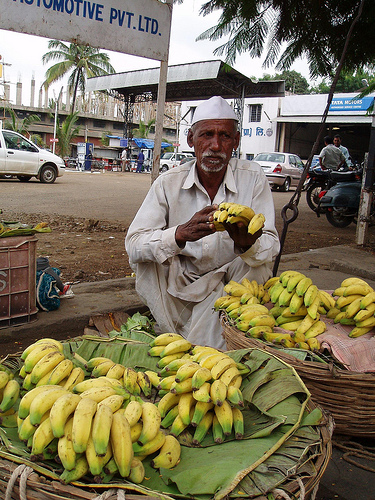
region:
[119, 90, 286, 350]
The man is dressed in white.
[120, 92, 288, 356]
The man is holding a bunch of bananas.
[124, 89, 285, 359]
The man is wearing a hat.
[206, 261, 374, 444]
The large basket has bananas on top.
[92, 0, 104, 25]
The letter is blue.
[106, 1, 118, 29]
The letter is blue.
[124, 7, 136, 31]
The letter is blue.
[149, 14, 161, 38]
The letter is blue.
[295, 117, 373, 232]
The men are standing by the motorcycle.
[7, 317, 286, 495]
bunches of bananas for sale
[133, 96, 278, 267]
man holding bananas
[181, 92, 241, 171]
man wearing a white hat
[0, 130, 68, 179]
white vehicle on the road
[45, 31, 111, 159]
tall palm tree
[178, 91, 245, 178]
man with a white beard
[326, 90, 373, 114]
blue sign on the building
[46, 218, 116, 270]
rocky dirt ground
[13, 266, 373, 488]
bananas sitting on stands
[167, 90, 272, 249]
Man wearing white cap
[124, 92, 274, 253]
Man in white cap holding bananas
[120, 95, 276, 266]
Man wearing white shirt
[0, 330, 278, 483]
yellow bananas sitting on banana leaves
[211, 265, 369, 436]
wicker basket full of yellow bananas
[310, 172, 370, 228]
rear tire of blue motor scooter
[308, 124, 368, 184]
man in white shirt next to man in blue shirt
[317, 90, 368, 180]
blue sign on front of building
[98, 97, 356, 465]
man in white selling bananas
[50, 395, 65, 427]
yellow banana in banana bunch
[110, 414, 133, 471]
yellow banana in banana bunch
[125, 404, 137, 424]
yellow banana in banana bunch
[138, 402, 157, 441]
yellow banana in banana bunch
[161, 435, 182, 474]
yellow banana in banana bunch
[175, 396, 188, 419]
yellow banana in banana bunch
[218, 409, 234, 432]
yellow banana in banana bunch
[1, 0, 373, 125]
bright lights over trees and buildings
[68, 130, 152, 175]
people standing in front on an outdoor cafe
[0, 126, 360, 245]
vehicles parked on flat paved road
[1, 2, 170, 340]
sign above dirt patch with litter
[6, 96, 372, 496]
man with display of bunches of bananas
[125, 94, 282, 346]
man holding bananas with both hands in front of body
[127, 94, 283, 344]
man in loose clothing by large woven baskets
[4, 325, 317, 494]
green and yellow bananas on top of green leaves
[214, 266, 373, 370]
bananas curved over pink plaid fabric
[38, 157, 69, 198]
a tire on a car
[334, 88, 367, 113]
a sign on a building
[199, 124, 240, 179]
a man with a beard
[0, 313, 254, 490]
a group of bananas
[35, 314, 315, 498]
leaves under the bananas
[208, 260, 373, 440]
bananas are in a a basket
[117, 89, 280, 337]
man holding a banana bunch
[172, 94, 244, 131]
man wearing a white hat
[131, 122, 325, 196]
cars in the background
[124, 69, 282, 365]
man sitting next to basket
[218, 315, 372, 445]
the basket is brown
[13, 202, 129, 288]
debris on the ground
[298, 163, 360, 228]
a motor bike on the side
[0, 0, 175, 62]
white sign with blue letters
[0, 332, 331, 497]
wicker basket with yellow bananas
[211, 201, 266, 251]
bananas in man's hand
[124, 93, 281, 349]
man wearing white cloths